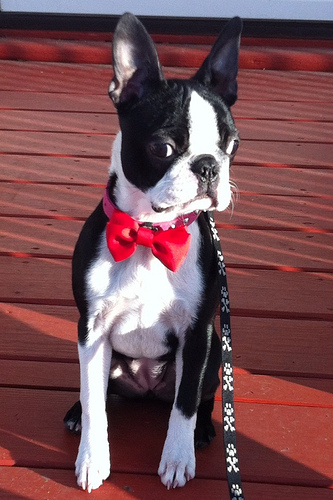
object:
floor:
[240, 49, 326, 487]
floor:
[1, 33, 76, 495]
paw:
[69, 433, 116, 495]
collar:
[98, 187, 203, 233]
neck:
[89, 167, 209, 236]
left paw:
[149, 441, 200, 487]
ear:
[109, 9, 167, 116]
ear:
[202, 9, 244, 107]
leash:
[203, 207, 254, 498]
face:
[133, 98, 238, 216]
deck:
[2, 35, 327, 497]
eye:
[135, 128, 190, 160]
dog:
[63, 12, 246, 488]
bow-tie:
[102, 191, 200, 273]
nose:
[192, 157, 225, 183]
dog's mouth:
[168, 184, 231, 213]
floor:
[233, 134, 328, 353]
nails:
[159, 469, 180, 498]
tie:
[105, 210, 190, 273]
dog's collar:
[95, 168, 206, 232]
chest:
[107, 305, 179, 358]